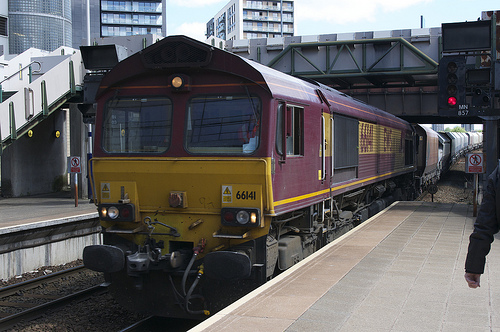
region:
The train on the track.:
[113, 62, 439, 239]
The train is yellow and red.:
[106, 37, 428, 198]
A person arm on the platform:
[442, 151, 499, 283]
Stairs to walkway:
[13, 52, 67, 137]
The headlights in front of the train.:
[82, 203, 291, 225]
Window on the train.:
[274, 101, 319, 153]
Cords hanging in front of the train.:
[181, 247, 215, 323]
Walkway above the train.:
[143, 29, 459, 80]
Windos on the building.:
[102, 4, 152, 36]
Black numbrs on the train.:
[236, 174, 268, 211]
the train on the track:
[82, 34, 481, 316]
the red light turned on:
[448, 95, 455, 105]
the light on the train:
[171, 77, 181, 87]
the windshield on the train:
[182, 94, 262, 154]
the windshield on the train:
[101, 95, 173, 152]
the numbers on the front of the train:
[235, 188, 257, 201]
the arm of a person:
[463, 156, 498, 288]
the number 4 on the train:
[247, 189, 253, 199]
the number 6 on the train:
[235, 189, 240, 199]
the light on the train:
[250, 211, 256, 222]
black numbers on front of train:
[229, 182, 271, 204]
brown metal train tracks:
[14, 273, 74, 320]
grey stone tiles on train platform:
[371, 255, 446, 320]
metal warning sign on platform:
[453, 148, 462, 173]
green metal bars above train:
[288, 32, 430, 76]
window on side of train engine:
[269, 92, 318, 167]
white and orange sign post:
[68, 169, 86, 214]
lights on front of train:
[218, 207, 258, 209]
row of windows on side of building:
[101, 2, 160, 29]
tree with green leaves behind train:
[438, 119, 468, 141]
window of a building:
[105, 13, 115, 26]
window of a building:
[115, 13, 123, 21]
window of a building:
[122, 18, 134, 24]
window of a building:
[44, 21, 53, 30]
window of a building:
[21, 32, 42, 47]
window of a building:
[15, 17, 35, 32]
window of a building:
[245, 2, 260, 14]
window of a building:
[219, 15, 230, 25]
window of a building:
[256, 21, 270, 26]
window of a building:
[243, 32, 261, 38]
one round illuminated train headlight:
[167, 71, 186, 87]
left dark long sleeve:
[464, 168, 499, 279]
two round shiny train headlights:
[92, 202, 261, 225]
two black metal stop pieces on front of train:
[78, 243, 253, 284]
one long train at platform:
[81, 35, 486, 313]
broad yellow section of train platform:
[199, 182, 430, 330]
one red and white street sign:
[467, 149, 482, 175]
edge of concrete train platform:
[5, 203, 85, 308]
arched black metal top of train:
[93, 28, 263, 85]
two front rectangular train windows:
[88, 91, 265, 165]